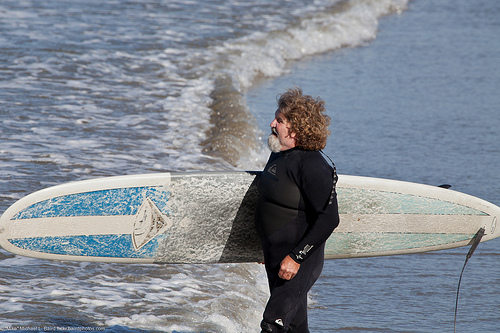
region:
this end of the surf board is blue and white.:
[4, 174, 174, 269]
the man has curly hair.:
[266, 88, 331, 133]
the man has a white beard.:
[264, 125, 283, 154]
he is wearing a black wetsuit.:
[259, 91, 339, 320]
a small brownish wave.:
[168, 31, 270, 166]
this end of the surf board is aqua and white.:
[352, 176, 498, 254]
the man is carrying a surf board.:
[2, 173, 498, 263]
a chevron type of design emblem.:
[262, 158, 281, 180]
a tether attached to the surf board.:
[449, 224, 493, 331]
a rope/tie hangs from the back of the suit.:
[317, 143, 341, 208]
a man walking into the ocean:
[231, 92, 329, 332]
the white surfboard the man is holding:
[3, 170, 498, 273]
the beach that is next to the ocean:
[286, 0, 496, 328]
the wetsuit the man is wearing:
[253, 147, 347, 331]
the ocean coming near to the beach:
[0, 1, 322, 326]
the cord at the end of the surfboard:
[448, 232, 478, 331]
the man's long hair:
[283, 85, 334, 153]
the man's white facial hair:
[258, 127, 280, 151]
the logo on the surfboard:
[127, 200, 163, 250]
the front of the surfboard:
[11, 176, 166, 262]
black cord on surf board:
[457, 227, 492, 290]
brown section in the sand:
[213, 92, 247, 147]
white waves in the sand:
[264, 27, 361, 42]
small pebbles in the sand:
[12, 282, 123, 319]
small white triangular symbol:
[115, 192, 195, 227]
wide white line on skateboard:
[360, 198, 472, 246]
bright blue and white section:
[30, 195, 118, 217]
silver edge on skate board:
[149, 160, 259, 190]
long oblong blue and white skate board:
[23, 166, 478, 281]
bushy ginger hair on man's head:
[252, 65, 369, 176]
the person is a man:
[223, 69, 354, 327]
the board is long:
[12, 154, 494, 295]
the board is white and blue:
[22, 162, 498, 272]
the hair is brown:
[253, 73, 341, 171]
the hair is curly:
[257, 74, 338, 175]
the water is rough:
[79, 15, 282, 140]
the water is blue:
[395, 70, 470, 151]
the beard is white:
[257, 117, 299, 162]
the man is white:
[192, 72, 367, 327]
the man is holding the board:
[20, 80, 497, 290]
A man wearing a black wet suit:
[246, 74, 346, 331]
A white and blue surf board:
[4, 174, 490, 281]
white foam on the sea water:
[8, 65, 203, 159]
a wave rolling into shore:
[236, 0, 431, 85]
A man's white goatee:
[251, 111, 299, 158]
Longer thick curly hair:
[277, 74, 338, 154]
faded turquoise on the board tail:
[331, 167, 463, 271]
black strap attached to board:
[438, 199, 497, 331]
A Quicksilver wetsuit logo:
[265, 158, 281, 183]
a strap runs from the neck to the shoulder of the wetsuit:
[297, 141, 357, 227]